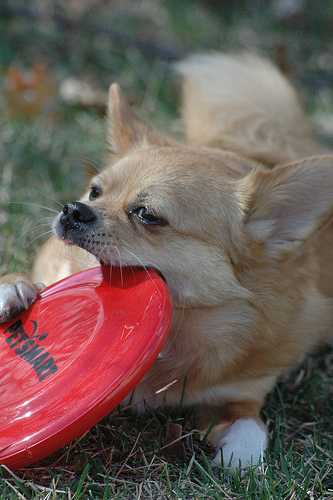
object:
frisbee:
[5, 251, 181, 462]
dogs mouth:
[55, 199, 181, 292]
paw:
[212, 418, 269, 473]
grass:
[214, 468, 308, 493]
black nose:
[59, 202, 98, 229]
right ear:
[98, 92, 141, 138]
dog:
[30, 112, 332, 388]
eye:
[132, 201, 167, 228]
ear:
[242, 153, 332, 261]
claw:
[12, 285, 33, 313]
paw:
[4, 269, 46, 339]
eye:
[87, 182, 104, 202]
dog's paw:
[0, 268, 49, 332]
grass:
[13, 46, 108, 157]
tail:
[210, 63, 278, 141]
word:
[3, 318, 67, 390]